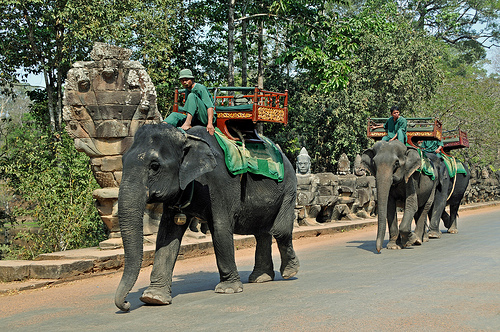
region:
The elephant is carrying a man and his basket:
[101, 65, 305, 311]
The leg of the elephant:
[140, 229, 186, 315]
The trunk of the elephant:
[111, 180, 147, 310]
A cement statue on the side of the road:
[63, 37, 161, 244]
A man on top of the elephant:
[158, 67, 218, 134]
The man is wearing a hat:
[176, 64, 196, 81]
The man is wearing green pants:
[164, 97, 209, 134]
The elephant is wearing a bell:
[152, 180, 201, 227]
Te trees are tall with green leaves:
[164, 5, 359, 67]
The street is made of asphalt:
[270, 279, 468, 329]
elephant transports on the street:
[24, 10, 492, 287]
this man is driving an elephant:
[76, 71, 303, 311]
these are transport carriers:
[346, 101, 498, 280]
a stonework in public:
[55, 22, 167, 122]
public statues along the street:
[287, 138, 381, 237]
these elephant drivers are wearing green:
[145, 63, 478, 176]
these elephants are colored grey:
[73, 123, 463, 266]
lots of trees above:
[11, 3, 491, 49]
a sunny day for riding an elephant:
[5, 49, 498, 292]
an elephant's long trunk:
[108, 157, 153, 317]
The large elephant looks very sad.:
[114, 120, 299, 311]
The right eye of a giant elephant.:
[148, 159, 161, 173]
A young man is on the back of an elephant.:
[162, 67, 215, 136]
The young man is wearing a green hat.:
[177, 65, 193, 81]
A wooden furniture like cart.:
[171, 85, 288, 142]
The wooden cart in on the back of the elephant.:
[366, 115, 443, 147]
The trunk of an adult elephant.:
[112, 170, 147, 311]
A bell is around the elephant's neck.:
[171, 207, 188, 227]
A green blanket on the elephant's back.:
[212, 126, 284, 181]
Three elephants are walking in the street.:
[113, 121, 471, 311]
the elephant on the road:
[53, 58, 329, 330]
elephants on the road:
[344, 103, 499, 247]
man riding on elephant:
[117, 55, 222, 126]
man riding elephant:
[380, 110, 420, 145]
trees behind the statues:
[122, 15, 477, 100]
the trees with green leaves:
[175, 5, 440, 80]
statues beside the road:
[285, 146, 480, 203]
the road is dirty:
[41, 290, 76, 310]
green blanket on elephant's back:
[206, 135, 291, 180]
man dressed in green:
[157, 62, 221, 131]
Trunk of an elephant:
[113, 171, 145, 311]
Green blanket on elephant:
[211, 127, 291, 180]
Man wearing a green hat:
[175, 65, 196, 93]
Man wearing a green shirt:
[383, 103, 408, 142]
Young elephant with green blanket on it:
[113, 120, 302, 311]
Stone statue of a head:
[293, 145, 315, 175]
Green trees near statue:
[3, 113, 110, 255]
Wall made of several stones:
[300, 175, 373, 225]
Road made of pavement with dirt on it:
[317, 257, 453, 313]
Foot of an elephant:
[139, 277, 174, 309]